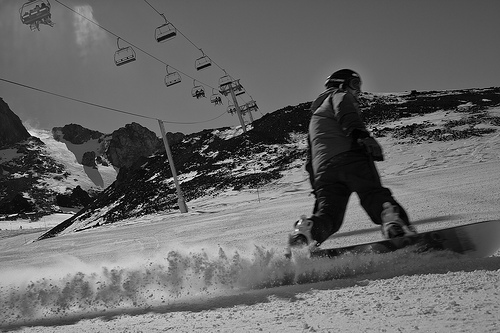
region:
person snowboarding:
[258, 64, 499, 297]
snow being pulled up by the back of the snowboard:
[8, 239, 383, 319]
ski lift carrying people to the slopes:
[11, 1, 273, 148]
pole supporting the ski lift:
[153, 118, 194, 218]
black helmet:
[324, 60, 367, 100]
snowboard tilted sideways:
[267, 223, 494, 282]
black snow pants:
[311, 161, 394, 240]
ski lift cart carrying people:
[19, 3, 56, 33]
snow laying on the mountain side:
[38, 129, 123, 210]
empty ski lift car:
[148, 22, 179, 47]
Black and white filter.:
[4, 6, 496, 331]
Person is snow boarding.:
[281, 57, 471, 279]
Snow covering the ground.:
[2, 113, 494, 327]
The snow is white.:
[10, 161, 487, 327]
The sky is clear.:
[5, 5, 490, 137]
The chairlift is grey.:
[7, 0, 260, 120]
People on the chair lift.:
[182, 75, 254, 124]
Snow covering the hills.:
[7, 79, 494, 179]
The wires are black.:
[2, 77, 218, 132]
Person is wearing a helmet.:
[317, 57, 363, 102]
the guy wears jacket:
[240, 41, 441, 267]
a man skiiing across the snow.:
[283, 60, 425, 267]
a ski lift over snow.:
[0, 3, 267, 148]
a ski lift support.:
[152, 87, 191, 221]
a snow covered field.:
[0, 114, 497, 329]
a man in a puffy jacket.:
[308, 85, 382, 189]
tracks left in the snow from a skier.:
[0, 238, 312, 325]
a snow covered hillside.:
[0, 85, 497, 227]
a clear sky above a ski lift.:
[0, 6, 497, 121]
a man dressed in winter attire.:
[278, 20, 428, 265]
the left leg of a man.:
[364, 167, 416, 276]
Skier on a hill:
[271, 56, 431, 261]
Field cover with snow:
[20, 140, 497, 332]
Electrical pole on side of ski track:
[151, 101, 201, 218]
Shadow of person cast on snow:
[352, 205, 469, 242]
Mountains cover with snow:
[3, 98, 175, 193]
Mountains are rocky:
[5, 96, 167, 196]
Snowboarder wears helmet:
[275, 58, 420, 248]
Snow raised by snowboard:
[12, 232, 315, 323]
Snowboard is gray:
[256, 212, 497, 284]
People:
[16, 3, 63, 38]